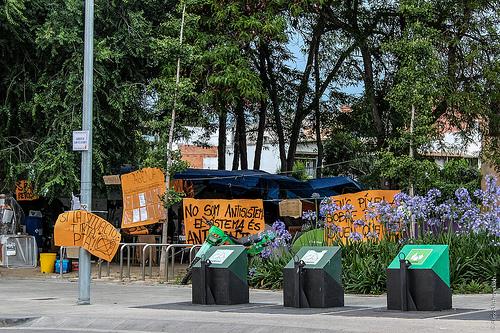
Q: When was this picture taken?
A: Daytime.